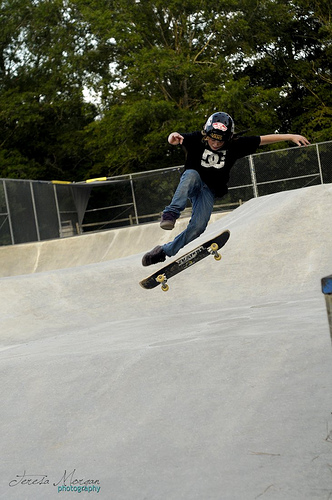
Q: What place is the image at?
A: It is at the park.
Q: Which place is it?
A: It is a park.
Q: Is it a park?
A: Yes, it is a park.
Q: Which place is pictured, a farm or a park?
A: It is a park.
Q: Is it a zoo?
A: No, it is a park.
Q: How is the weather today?
A: It is clear.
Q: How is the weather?
A: It is clear.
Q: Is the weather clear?
A: Yes, it is clear.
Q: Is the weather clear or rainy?
A: It is clear.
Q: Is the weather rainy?
A: No, it is clear.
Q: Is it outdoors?
A: Yes, it is outdoors.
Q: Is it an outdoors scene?
A: Yes, it is outdoors.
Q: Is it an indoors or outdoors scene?
A: It is outdoors.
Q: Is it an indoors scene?
A: No, it is outdoors.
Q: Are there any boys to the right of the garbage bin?
A: Yes, there is a boy to the right of the garbage bin.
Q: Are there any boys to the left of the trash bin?
A: No, the boy is to the right of the trash bin.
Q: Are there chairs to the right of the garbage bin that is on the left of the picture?
A: No, there is a boy to the right of the trash can.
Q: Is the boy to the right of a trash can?
A: Yes, the boy is to the right of a trash can.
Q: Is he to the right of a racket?
A: No, the boy is to the right of a trash can.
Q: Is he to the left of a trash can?
A: No, the boy is to the right of a trash can.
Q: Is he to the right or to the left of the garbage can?
A: The boy is to the right of the garbage can.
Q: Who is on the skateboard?
A: The boy is on the skateboard.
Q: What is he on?
A: The boy is on the skateboard.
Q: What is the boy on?
A: The boy is on the skateboard.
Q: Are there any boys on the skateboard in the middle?
A: Yes, there is a boy on the skateboard.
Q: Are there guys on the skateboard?
A: No, there is a boy on the skateboard.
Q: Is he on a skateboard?
A: Yes, the boy is on a skateboard.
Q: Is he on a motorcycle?
A: No, the boy is on a skateboard.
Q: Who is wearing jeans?
A: The boy is wearing jeans.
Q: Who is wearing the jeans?
A: The boy is wearing jeans.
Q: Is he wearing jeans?
A: Yes, the boy is wearing jeans.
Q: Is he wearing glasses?
A: No, the boy is wearing jeans.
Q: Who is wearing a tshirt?
A: The boy is wearing a tshirt.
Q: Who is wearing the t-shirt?
A: The boy is wearing a tshirt.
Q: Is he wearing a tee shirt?
A: Yes, the boy is wearing a tee shirt.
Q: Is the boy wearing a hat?
A: No, the boy is wearing a tee shirt.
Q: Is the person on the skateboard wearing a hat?
A: No, the boy is wearing a tee shirt.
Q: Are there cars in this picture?
A: No, there are no cars.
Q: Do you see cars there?
A: No, there are no cars.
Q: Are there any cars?
A: No, there are no cars.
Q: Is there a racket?
A: No, there are no rackets.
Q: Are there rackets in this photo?
A: No, there are no rackets.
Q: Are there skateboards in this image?
A: Yes, there is a skateboard.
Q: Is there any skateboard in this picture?
A: Yes, there is a skateboard.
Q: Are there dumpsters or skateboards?
A: Yes, there is a skateboard.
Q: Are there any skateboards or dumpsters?
A: Yes, there is a skateboard.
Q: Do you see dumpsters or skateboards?
A: Yes, there is a skateboard.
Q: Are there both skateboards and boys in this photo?
A: Yes, there are both a skateboard and a boy.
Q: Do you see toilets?
A: No, there are no toilets.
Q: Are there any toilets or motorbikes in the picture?
A: No, there are no toilets or motorbikes.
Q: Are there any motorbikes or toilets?
A: No, there are no toilets or motorbikes.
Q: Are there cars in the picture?
A: No, there are no cars.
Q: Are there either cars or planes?
A: No, there are no cars or planes.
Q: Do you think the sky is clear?
A: Yes, the sky is clear.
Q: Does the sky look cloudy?
A: No, the sky is clear.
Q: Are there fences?
A: Yes, there is a fence.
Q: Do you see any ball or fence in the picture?
A: Yes, there is a fence.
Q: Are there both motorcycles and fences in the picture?
A: No, there is a fence but no motorcycles.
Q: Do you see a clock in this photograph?
A: No, there are no clocks.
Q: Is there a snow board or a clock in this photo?
A: No, there are no clocks or snowboards.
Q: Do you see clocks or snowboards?
A: No, there are no clocks or snowboards.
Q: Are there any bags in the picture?
A: No, there are no bags.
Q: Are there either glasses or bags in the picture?
A: No, there are no bags or glasses.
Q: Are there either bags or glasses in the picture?
A: No, there are no bags or glasses.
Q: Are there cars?
A: No, there are no cars.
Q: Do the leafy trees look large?
A: Yes, the trees are large.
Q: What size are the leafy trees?
A: The trees are large.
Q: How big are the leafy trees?
A: The trees are large.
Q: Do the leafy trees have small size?
A: No, the trees are large.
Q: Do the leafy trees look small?
A: No, the trees are large.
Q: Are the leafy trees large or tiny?
A: The trees are large.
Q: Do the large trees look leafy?
A: Yes, the trees are leafy.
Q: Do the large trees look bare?
A: No, the trees are leafy.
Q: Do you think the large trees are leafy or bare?
A: The trees are leafy.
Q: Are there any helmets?
A: Yes, there is a helmet.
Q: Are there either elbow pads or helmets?
A: Yes, there is a helmet.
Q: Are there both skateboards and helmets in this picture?
A: Yes, there are both a helmet and a skateboard.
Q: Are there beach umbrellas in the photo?
A: No, there are no beach umbrellas.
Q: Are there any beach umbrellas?
A: No, there are no beach umbrellas.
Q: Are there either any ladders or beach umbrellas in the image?
A: No, there are no beach umbrellas or ladders.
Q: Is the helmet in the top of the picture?
A: Yes, the helmet is in the top of the image.